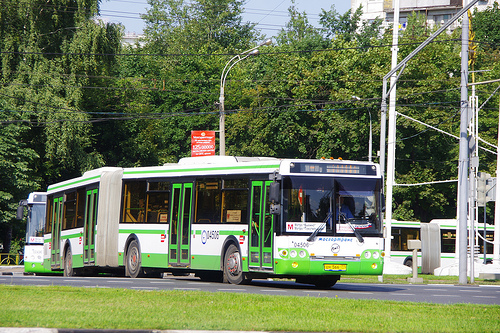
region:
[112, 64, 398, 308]
a bus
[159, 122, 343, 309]
a bus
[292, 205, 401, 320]
a bus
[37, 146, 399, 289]
bus on a street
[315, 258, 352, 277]
front licence plate on a vehicle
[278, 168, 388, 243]
front windshield on a vehicle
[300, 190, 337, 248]
windshield wiper on a vehicle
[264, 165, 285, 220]
side rear view mirror on a vehicle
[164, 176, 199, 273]
side doors on a bus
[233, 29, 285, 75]
streetlights on a pole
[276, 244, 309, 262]
front headlight on a vehicle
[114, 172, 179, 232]
side windows on a vehicle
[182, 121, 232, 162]
red and white sign on a pole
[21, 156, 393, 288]
a long bus driving down the road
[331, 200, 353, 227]
the driver sitting in the bus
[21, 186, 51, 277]
the front end of another bus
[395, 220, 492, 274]
another long bus on the road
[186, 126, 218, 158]
a red sign attached to the wall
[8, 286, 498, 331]
the green grass next to the road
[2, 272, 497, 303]
the road the buses are driving on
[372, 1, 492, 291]
poles next to the road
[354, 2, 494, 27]
a building behind the trees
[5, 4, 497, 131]
power lines above the buses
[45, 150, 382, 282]
a green and white double bus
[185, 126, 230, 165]
a red banner hanging from the pole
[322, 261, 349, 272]
the bus's yellow lisence plate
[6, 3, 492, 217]
the tall green trees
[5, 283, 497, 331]
green grass near the road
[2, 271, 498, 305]
the street marked with white lines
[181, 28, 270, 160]
a street light with a red sign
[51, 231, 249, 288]
three outer wheels of the bus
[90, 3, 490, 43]
tall buildings behind the trees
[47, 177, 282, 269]
four sets of green double doors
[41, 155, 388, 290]
The bus in the front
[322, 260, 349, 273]
The yellow license plate of the front bus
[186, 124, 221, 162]
The large red sign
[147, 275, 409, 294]
The shadow of the front bus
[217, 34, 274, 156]
The street light connected to the red sign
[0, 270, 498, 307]
The road the buses are on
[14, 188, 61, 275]
The second bus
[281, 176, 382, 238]
The windshield of the front bus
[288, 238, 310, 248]
The number on the front of the first bus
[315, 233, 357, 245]
The blue writing on the front of the bus